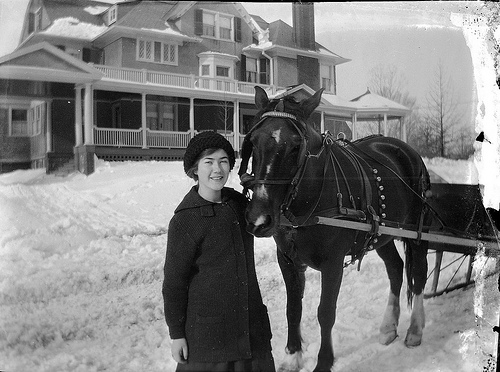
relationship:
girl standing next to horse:
[161, 130, 276, 371] [227, 79, 479, 359]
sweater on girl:
[159, 182, 276, 361] [161, 130, 276, 371]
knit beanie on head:
[183, 130, 238, 175] [197, 147, 231, 189]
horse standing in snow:
[240, 86, 434, 371] [14, 153, 389, 370]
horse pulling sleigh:
[212, 78, 426, 368] [322, 150, 479, 257]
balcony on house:
[85, 60, 285, 96] [0, 0, 410, 175]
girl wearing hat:
[161, 130, 276, 371] [181, 130, 241, 167]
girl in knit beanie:
[161, 130, 276, 371] [183, 131, 235, 172]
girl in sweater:
[161, 130, 276, 371] [163, 184, 270, 359]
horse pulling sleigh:
[240, 86, 434, 371] [425, 181, 499, 303]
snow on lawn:
[3, 160, 183, 370] [3, 147, 433, 356]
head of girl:
[168, 129, 228, 190] [161, 130, 276, 371]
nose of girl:
[211, 161, 223, 174] [161, 130, 276, 371]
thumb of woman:
[178, 341, 193, 359] [166, 120, 281, 369]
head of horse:
[241, 83, 324, 238] [240, 86, 434, 371]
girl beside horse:
[166, 134, 305, 371] [240, 86, 434, 371]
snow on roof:
[52, 18, 99, 38] [13, 17, 109, 48]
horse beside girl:
[240, 86, 434, 371] [161, 130, 276, 369]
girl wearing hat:
[161, 130, 276, 371] [180, 125, 239, 167]